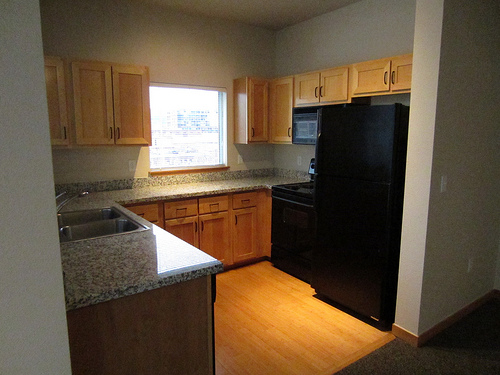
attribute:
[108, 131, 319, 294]
kitchen — here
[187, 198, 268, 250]
cabinets — under, pale, wooden, here, new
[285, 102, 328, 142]
microwave — above, black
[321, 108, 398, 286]
refrigerator — black, new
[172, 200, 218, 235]
handles — black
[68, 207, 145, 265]
sink — steel, here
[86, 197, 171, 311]
counter — granite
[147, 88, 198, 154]
window — covered, over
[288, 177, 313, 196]
stove — black, beside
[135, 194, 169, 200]
granite — speckled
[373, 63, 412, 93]
knobs — metal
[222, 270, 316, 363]
tile — beige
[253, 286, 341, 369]
floor — pale, wood, hardwood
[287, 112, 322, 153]
oven — over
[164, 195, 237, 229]
drawers — under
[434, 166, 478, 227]
light — white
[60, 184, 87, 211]
faucet — steel